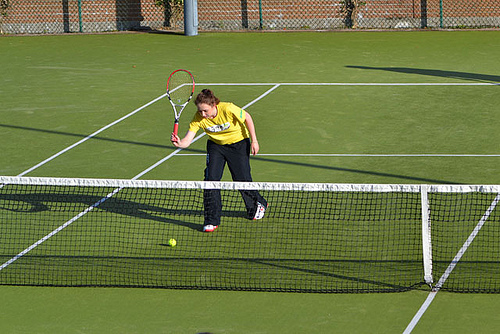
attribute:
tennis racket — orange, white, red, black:
[164, 69, 196, 144]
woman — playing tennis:
[172, 88, 269, 232]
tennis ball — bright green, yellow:
[166, 238, 176, 246]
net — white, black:
[0, 176, 499, 294]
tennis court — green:
[0, 1, 498, 333]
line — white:
[175, 151, 500, 159]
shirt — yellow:
[188, 102, 248, 145]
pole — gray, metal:
[183, 0, 199, 37]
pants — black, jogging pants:
[203, 140, 269, 226]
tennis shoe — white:
[203, 224, 220, 231]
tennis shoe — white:
[256, 203, 266, 221]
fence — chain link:
[1, 1, 499, 27]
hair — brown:
[194, 88, 221, 108]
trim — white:
[1, 174, 499, 193]